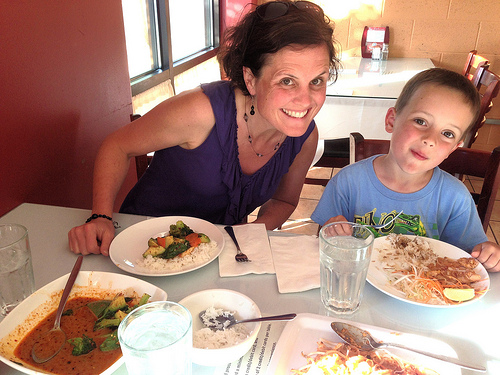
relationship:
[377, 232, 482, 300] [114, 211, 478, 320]
food on plate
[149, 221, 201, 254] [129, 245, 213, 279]
vegetables over rice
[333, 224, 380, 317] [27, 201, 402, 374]
glass on table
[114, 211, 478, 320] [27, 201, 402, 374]
plate on table